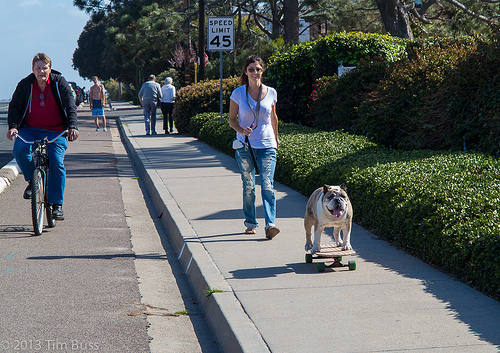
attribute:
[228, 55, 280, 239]
woman — walking, smiling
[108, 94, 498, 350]
sidewalk — concrete, gray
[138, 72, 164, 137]
old man — walking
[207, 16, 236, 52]
sign — black, white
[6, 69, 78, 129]
jacket — black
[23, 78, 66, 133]
shirt — red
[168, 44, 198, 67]
flowers — pink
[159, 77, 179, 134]
old lady — walking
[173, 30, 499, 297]
bushes — green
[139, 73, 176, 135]
elderly — walking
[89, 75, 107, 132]
man — shirtless